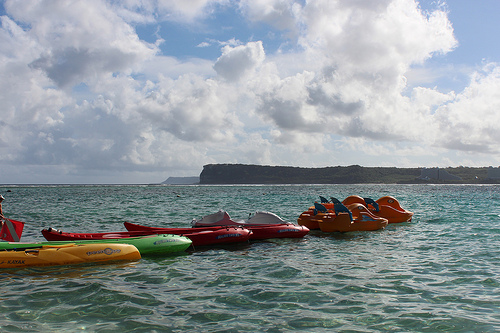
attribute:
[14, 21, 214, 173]
clouds — white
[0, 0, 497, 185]
clouds — white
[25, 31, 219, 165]
clouds — white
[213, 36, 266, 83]
cloud — white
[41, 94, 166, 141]
cloud — white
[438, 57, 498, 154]
cloud — white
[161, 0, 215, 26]
cloud — white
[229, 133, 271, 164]
cloud — white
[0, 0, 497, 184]
sky — blue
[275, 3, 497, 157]
clouds — white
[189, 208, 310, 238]
watercraft — red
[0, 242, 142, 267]
tube — yellow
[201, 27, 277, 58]
clouds — white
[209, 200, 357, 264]
tube — red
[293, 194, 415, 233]
paddle boats — orange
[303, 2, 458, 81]
cloud — white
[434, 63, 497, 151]
cloud — white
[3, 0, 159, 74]
cloud — white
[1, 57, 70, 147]
cloud — white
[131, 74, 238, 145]
cloud — white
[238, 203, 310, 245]
raft — red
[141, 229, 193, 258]
colored raft — green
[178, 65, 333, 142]
clouds — white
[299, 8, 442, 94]
clouds — white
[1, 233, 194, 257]
tube — green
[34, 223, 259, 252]
raft — red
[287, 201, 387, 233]
raft — red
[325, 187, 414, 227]
raft — red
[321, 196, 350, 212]
seats — blue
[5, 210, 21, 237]
material — red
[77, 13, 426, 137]
sky — blue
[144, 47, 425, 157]
sky — blue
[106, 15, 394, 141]
sky — blue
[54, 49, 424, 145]
sky — blue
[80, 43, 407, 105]
sky — blue